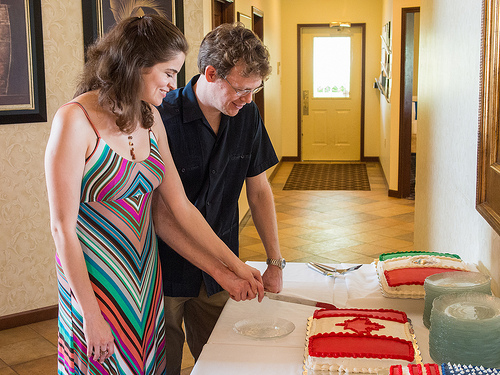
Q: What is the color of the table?
A: White.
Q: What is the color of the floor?
A: Brown.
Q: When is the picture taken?
A: Daytime.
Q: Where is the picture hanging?
A: In the wall.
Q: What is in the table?
A: Cake.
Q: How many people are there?
A: 2.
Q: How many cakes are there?
A: 3.